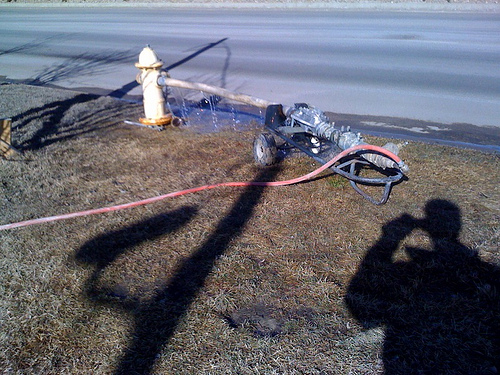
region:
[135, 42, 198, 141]
this is a yellow fire hydrant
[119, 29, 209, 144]
the paint on the hydrant is faded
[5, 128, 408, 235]
a long and thin red hose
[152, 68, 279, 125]
this is a thick hose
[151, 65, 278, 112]
this hose is short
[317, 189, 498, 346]
the shadow of a man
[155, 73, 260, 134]
water is dripping from the thick hose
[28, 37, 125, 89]
this is a shadow of a tree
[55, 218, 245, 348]
the grass is browned and dried out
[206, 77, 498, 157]
the pavement is wet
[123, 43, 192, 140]
this is a fire hydrant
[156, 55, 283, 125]
a hose attached to the hydrant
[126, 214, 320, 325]
the grass is brown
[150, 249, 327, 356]
the grass is dry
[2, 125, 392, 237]
a long and red hose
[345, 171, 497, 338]
the shadow of a person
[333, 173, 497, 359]
the shadow of a person taking the picture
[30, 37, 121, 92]
shadow of tree branches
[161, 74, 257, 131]
water is dripping from the hose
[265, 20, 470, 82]
this is part of the street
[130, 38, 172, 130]
this is a hydrant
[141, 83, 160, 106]
the hydrant is white in color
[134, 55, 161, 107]
ther hydrant is metallic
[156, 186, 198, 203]
the pipe is red in color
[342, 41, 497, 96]
this is a water body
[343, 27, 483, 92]
the water is calm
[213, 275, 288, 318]
the grass is dry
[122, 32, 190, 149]
this is a fire hydrant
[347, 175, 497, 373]
this is a shadow of a person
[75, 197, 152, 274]
this is a shadow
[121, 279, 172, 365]
this is a shadow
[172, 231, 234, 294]
this is a shadow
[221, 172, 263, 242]
this is a shadow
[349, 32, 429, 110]
this is a body of water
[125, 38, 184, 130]
A white fire hydrant by the road.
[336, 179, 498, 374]
A person's shadow taking a picture.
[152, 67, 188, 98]
A dirty hose connected to the hydrant.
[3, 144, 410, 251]
A long red hose connected to a machine.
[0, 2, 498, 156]
A cement road in the back of the photo.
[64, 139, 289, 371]
A long thin shadow.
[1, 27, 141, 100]
Shadows of two bushes by the street.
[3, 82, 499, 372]
A big patch of dead grass.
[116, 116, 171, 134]
A tool laying on the ground by the hydrant.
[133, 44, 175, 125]
Mostly white fire hydrant.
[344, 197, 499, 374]
Shadow of a person on the grass.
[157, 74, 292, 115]
Smaller hose coming out of a hydrant side.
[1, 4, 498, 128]
A paved grey road.